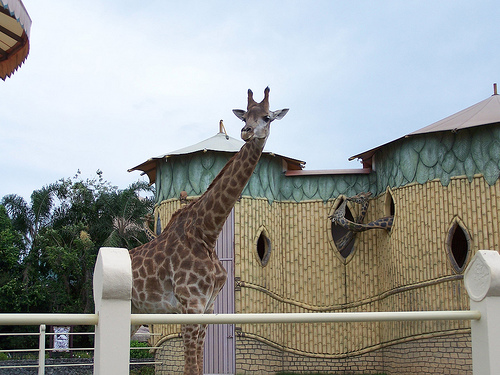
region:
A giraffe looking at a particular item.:
[125, 82, 287, 372]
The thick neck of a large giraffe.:
[156, 140, 262, 235]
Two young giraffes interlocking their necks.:
[325, 185, 390, 250]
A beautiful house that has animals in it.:
[125, 80, 496, 372]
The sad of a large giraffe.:
[230, 82, 290, 144]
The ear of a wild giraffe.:
[272, 105, 291, 120]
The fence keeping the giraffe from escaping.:
[0, 245, 498, 374]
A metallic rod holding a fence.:
[130, 308, 480, 325]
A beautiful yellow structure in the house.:
[149, 172, 498, 357]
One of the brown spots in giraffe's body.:
[177, 250, 194, 272]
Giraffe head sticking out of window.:
[346, 186, 386, 281]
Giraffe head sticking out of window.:
[332, 189, 375, 244]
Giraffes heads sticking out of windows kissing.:
[326, 179, 398, 256]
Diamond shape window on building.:
[441, 216, 478, 286]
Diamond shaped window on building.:
[240, 219, 277, 259]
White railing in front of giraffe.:
[97, 283, 427, 347]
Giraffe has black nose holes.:
[236, 119, 273, 146]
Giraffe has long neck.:
[181, 157, 266, 241]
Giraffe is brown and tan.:
[141, 186, 246, 289]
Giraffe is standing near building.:
[126, 169, 258, 286]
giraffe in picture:
[0, 72, 314, 317]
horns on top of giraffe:
[223, 77, 297, 113]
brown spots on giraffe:
[138, 167, 304, 280]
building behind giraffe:
[211, 115, 459, 307]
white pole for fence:
[51, 291, 433, 363]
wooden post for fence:
[71, 237, 169, 340]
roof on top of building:
[176, 110, 273, 161]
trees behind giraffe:
[8, 152, 117, 365]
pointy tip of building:
[201, 109, 243, 141]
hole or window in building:
[228, 230, 288, 288]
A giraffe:
[78, 82, 278, 354]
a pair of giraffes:
[316, 180, 396, 250]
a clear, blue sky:
[2, 0, 497, 175]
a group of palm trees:
[6, 177, 153, 309]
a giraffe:
[138, 210, 158, 242]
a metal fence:
[5, 249, 499, 370]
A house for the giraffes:
[128, 117, 499, 356]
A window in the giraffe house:
[247, 220, 279, 273]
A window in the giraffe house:
[438, 207, 477, 273]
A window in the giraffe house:
[323, 190, 358, 265]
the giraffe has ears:
[226, 87, 342, 204]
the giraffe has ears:
[243, 56, 300, 131]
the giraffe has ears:
[161, 55, 328, 215]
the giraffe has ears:
[165, 35, 363, 365]